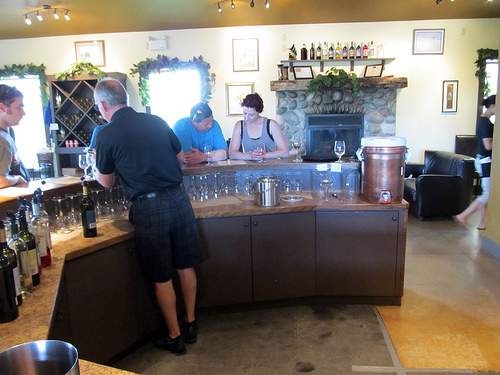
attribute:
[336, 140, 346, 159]
wine glass — clear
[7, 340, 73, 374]
bowl — metal, silver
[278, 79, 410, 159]
fireplace — stone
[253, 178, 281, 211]
bucket — silver, steel, shiny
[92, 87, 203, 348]
bartender — male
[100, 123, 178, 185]
shirt — black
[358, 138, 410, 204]
dispenser — thermal, insulated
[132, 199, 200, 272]
pants — black, plaid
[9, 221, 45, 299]
bottles — assorted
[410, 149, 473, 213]
chair — upholstered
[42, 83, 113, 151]
cubby — shelved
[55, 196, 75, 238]
glass — empty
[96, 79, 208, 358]
man — older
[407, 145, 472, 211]
couch — leather, black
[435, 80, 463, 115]
picture — framed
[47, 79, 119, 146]
wine rack — wooden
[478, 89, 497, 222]
woman — walking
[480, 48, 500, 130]
window — framed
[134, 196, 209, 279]
shorts — black, plaid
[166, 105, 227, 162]
man — sitting, standing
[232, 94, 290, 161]
woman — sitting, standing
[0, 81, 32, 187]
man — standing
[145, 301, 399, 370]
mat — non-slip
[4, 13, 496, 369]
room — rustic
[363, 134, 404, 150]
lid — white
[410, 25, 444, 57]
diploma — framed